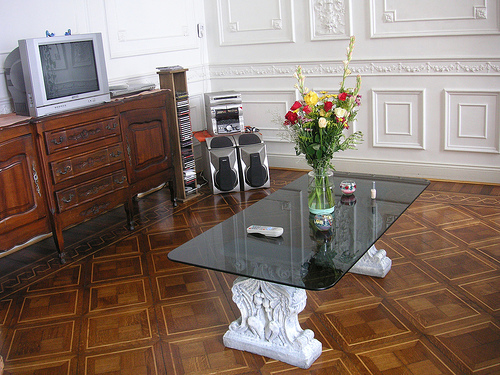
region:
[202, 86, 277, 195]
a sliver and black stereo system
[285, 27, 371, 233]
a glass vase with flowers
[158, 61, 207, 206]
a wood cd tower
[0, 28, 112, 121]
a silver tv console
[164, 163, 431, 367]
a rectangle glass coffee table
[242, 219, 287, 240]
a grey remote control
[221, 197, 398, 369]
white legs of a coffee table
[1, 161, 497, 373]
square brown design on the floor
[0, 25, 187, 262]
tv sitting on a wood desk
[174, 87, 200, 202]
a stack of different cds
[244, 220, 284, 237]
A gray TV remote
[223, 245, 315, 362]
An intricately designed table leg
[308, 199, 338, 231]
A small blue flower pot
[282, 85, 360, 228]
A vase of yellow, red, and white flowers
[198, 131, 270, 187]
A pair of speakers on the floor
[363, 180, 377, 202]
A small container of nail polish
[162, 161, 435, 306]
A glass table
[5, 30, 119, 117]
A silver box TV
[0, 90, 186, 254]
A wooden dresser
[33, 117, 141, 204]
Closed drawers on a wooden dresser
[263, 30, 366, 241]
A jar of different flowers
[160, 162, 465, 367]
A black/glass table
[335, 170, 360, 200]
A small pink candle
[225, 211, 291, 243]
A white/grey tv remote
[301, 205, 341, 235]
A small purple/blue candle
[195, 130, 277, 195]
Two silver colored speakers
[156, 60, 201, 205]
A wooden CD holder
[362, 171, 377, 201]
A small bottle of nail polish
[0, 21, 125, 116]
An older small tv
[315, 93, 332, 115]
A red rose in a jar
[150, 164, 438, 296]
THIS IS A TABLE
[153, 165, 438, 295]
THE TABLE HAS A GLASS TOP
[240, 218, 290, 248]
THE REMOTE IS ON THE TABLE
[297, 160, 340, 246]
THE VASE IS ON THE TABLE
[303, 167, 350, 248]
THE VASE IS GLASS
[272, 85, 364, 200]
THE FLOWERS ARE IN THE VASE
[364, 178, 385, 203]
THE NAIL POLISH IS ON THE TABLE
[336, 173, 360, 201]
THE BALL IS ON THE TABLE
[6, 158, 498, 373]
THE FLOOR IS DECORATIVE WOOD TILE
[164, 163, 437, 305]
THE GLASS TOP ON THE TABLE IS TINTED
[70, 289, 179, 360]
brown patterned wood of the floor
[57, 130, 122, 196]
brown carved wood of the cabinet drawers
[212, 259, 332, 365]
white stone support of the glass table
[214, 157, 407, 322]
black glass surface of the coffee table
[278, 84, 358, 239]
clear glass vase filled with flowers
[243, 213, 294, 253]
white remote control on the coffe table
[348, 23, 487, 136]
textured white walls of the room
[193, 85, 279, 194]
grey and black stereo system on the floor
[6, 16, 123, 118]
grey and black tv on top of the cabinet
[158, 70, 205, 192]
many cds stacked inside of a shelf